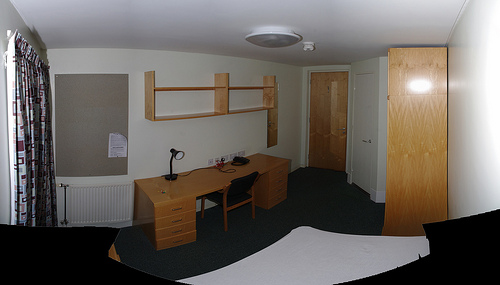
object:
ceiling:
[7, 0, 474, 67]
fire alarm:
[302, 41, 316, 51]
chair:
[200, 171, 263, 232]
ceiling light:
[244, 25, 302, 48]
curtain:
[9, 28, 57, 228]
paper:
[107, 132, 128, 158]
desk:
[132, 152, 292, 251]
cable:
[179, 161, 238, 176]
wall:
[446, 0, 500, 219]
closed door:
[308, 70, 349, 172]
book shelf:
[144, 70, 277, 122]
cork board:
[54, 73, 129, 177]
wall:
[43, 47, 305, 229]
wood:
[380, 46, 448, 237]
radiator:
[58, 181, 135, 228]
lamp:
[165, 147, 186, 180]